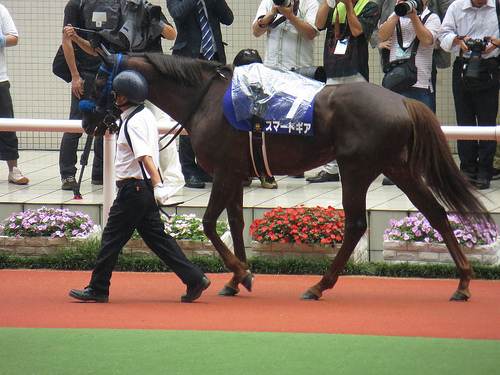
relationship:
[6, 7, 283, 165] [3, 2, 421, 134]
white brick brick planter white bridk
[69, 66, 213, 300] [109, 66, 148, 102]
man wearing helmet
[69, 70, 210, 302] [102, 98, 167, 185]
man wearing shirt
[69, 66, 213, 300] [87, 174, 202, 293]
man wearing pants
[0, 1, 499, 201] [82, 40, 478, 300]
people taking pictures of horse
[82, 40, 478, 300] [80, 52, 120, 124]
horse with harness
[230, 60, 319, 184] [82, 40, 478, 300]
blue saddle on horse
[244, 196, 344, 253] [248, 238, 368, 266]
red flowers in planter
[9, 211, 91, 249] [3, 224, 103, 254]
pink flowers in planter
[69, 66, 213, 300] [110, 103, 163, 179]
man wearing shirt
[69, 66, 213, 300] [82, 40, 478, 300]
man with horse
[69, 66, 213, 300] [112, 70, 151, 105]
man wearing helmet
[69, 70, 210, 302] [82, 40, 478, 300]
man guiding horse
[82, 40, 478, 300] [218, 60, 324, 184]
horse with saddle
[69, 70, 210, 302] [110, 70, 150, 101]
man wearing helmet